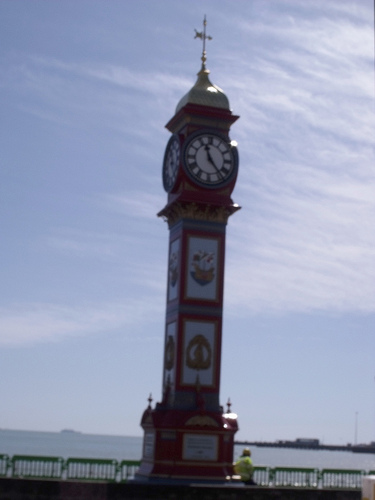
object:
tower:
[131, 13, 241, 484]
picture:
[165, 239, 181, 298]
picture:
[180, 321, 214, 386]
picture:
[161, 321, 178, 382]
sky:
[2, 1, 132, 423]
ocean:
[3, 427, 374, 468]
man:
[233, 447, 257, 483]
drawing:
[185, 236, 218, 301]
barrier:
[253, 467, 364, 488]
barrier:
[0, 460, 141, 485]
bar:
[274, 469, 299, 485]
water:
[54, 371, 115, 401]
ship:
[58, 425, 81, 434]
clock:
[160, 133, 183, 195]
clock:
[184, 125, 237, 188]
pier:
[3, 453, 374, 498]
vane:
[192, 15, 218, 59]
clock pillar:
[184, 234, 221, 300]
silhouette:
[54, 423, 85, 437]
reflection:
[184, 474, 259, 491]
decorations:
[181, 234, 223, 387]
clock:
[162, 126, 238, 193]